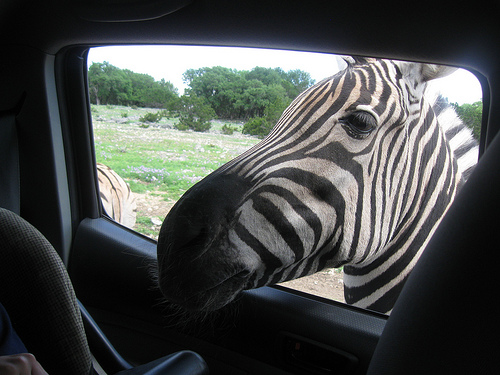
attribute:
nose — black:
[156, 185, 236, 275]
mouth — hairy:
[144, 254, 256, 320]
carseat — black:
[2, 201, 210, 374]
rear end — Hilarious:
[94, 157, 134, 223]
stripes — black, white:
[258, 163, 382, 235]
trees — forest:
[179, 84, 249, 102]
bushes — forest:
[157, 74, 228, 130]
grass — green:
[133, 139, 184, 175]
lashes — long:
[331, 83, 400, 152]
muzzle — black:
[159, 214, 240, 304]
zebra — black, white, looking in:
[165, 60, 479, 313]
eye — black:
[343, 110, 377, 138]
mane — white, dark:
[431, 90, 484, 184]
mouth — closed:
[164, 263, 250, 313]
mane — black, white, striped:
[427, 94, 477, 175]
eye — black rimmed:
[341, 108, 379, 136]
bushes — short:
[136, 105, 223, 137]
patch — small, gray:
[131, 166, 165, 175]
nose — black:
[153, 184, 228, 272]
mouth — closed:
[158, 265, 248, 316]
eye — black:
[336, 110, 378, 135]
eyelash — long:
[362, 110, 369, 127]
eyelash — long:
[364, 110, 370, 126]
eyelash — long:
[370, 115, 372, 127]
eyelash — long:
[357, 110, 363, 122]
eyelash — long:
[353, 111, 356, 119]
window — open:
[83, 45, 483, 317]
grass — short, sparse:
[91, 103, 263, 241]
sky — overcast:
[87, 44, 484, 106]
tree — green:
[87, 61, 116, 106]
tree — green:
[111, 77, 136, 106]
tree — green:
[183, 61, 217, 101]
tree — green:
[201, 61, 233, 91]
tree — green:
[232, 75, 268, 125]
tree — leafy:
[88, 60, 114, 104]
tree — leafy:
[105, 64, 125, 102]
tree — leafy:
[140, 80, 177, 109]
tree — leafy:
[182, 63, 210, 94]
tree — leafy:
[242, 64, 282, 86]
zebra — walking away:
[95, 160, 138, 230]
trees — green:
[89, 60, 310, 135]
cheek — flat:
[335, 166, 385, 261]